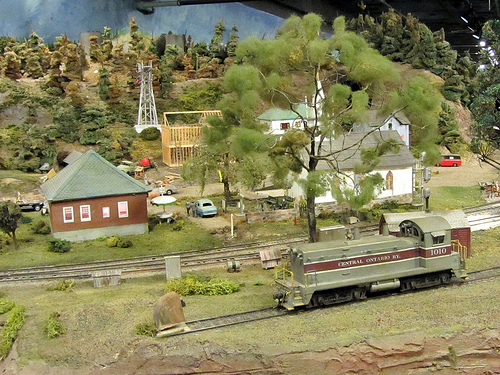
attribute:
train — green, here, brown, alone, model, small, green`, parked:
[273, 213, 473, 316]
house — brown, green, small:
[37, 149, 153, 248]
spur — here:
[151, 263, 500, 343]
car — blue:
[188, 196, 219, 219]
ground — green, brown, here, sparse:
[4, 38, 495, 365]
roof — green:
[37, 147, 158, 202]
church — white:
[281, 126, 419, 216]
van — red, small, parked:
[431, 151, 463, 169]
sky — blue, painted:
[2, 2, 359, 63]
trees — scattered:
[2, 10, 499, 247]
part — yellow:
[271, 258, 295, 289]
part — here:
[33, 206, 46, 214]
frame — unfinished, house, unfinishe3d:
[159, 107, 243, 169]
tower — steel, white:
[132, 56, 165, 136]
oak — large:
[181, 11, 448, 250]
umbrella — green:
[151, 190, 178, 215]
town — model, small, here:
[39, 73, 419, 247]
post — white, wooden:
[228, 211, 236, 243]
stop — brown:
[152, 287, 192, 338]